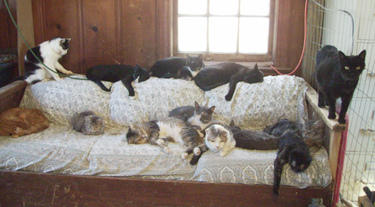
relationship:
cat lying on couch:
[265, 116, 313, 194] [0, 74, 347, 207]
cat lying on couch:
[202, 123, 233, 154] [0, 74, 347, 207]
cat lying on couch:
[167, 101, 215, 127] [0, 74, 347, 207]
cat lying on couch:
[129, 109, 197, 151] [0, 74, 347, 207]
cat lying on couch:
[71, 111, 105, 136] [0, 74, 347, 207]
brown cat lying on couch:
[0, 108, 49, 138] [0, 74, 347, 207]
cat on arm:
[319, 95, 349, 128] [312, 92, 344, 178]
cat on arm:
[315, 45, 365, 124] [336, 95, 351, 125]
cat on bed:
[71, 111, 105, 136] [7, 91, 358, 207]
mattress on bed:
[24, 133, 122, 174] [28, 102, 335, 199]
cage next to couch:
[328, 98, 374, 203] [7, 50, 346, 196]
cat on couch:
[315, 45, 365, 124] [0, 74, 347, 207]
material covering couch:
[49, 137, 139, 167] [0, 74, 347, 207]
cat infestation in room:
[315, 45, 365, 124] [3, 3, 374, 205]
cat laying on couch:
[126, 117, 205, 159] [0, 74, 347, 207]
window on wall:
[174, 4, 270, 55] [68, 4, 190, 74]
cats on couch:
[23, 39, 373, 168] [0, 67, 336, 189]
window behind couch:
[175, 0, 270, 55] [0, 74, 347, 207]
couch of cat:
[0, 74, 347, 207] [265, 116, 313, 194]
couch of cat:
[0, 74, 347, 207] [314, 47, 365, 117]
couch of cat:
[0, 74, 347, 207] [125, 116, 201, 154]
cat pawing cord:
[15, 33, 74, 84] [4, 3, 43, 71]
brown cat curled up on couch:
[0, 108, 49, 138] [0, 74, 347, 207]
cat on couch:
[70, 109, 106, 135] [0, 74, 347, 207]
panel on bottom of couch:
[4, 173, 337, 205] [0, 74, 347, 207]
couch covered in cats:
[10, 72, 323, 190] [0, 23, 371, 183]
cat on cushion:
[83, 62, 154, 101] [60, 73, 179, 149]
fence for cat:
[301, 1, 374, 205] [315, 45, 365, 124]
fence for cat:
[301, 1, 374, 205] [263, 116, 312, 199]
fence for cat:
[301, 1, 374, 205] [194, 59, 264, 102]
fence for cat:
[301, 1, 374, 205] [83, 62, 154, 101]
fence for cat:
[301, 1, 374, 205] [18, 35, 73, 84]